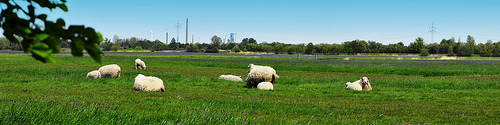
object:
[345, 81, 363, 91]
sheep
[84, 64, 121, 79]
sheep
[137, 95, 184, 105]
grass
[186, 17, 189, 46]
utility pole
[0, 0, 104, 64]
leaves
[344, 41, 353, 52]
leaves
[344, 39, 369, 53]
tree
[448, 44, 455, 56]
tree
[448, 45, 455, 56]
leaves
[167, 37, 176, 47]
leaves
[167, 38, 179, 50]
tree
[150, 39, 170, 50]
tree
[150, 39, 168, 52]
leaves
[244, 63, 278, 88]
sheep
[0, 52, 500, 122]
grass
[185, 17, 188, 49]
towers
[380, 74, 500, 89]
grass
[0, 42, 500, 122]
field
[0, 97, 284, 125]
grass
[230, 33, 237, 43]
building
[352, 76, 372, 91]
sheep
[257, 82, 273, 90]
sheep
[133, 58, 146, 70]
sheep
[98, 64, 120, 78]
sheep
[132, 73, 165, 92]
sheep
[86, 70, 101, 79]
sheep